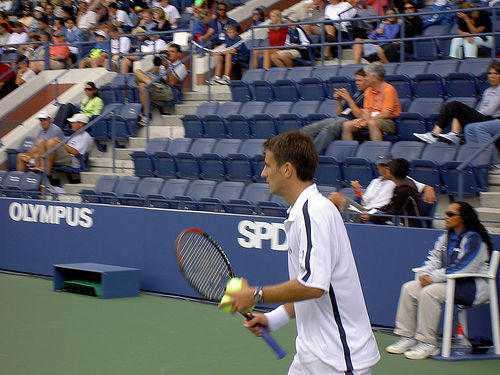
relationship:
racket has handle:
[171, 226, 289, 365] [255, 325, 286, 358]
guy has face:
[225, 142, 379, 371] [258, 147, 287, 196]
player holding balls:
[225, 142, 379, 371] [217, 279, 246, 310]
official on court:
[385, 204, 500, 374] [0, 274, 499, 370]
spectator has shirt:
[346, 66, 406, 147] [364, 84, 406, 117]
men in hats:
[25, 112, 94, 178] [35, 112, 94, 127]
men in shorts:
[25, 112, 94, 178] [15, 147, 77, 173]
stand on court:
[53, 257, 142, 299] [0, 274, 499, 370]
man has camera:
[129, 43, 189, 120] [150, 46, 172, 69]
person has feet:
[412, 54, 499, 143] [412, 126, 463, 148]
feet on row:
[412, 126, 463, 148] [142, 133, 475, 144]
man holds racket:
[225, 142, 379, 371] [171, 226, 289, 365]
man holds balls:
[225, 142, 379, 371] [217, 279, 246, 310]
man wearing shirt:
[341, 148, 403, 221] [353, 169, 434, 222]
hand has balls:
[221, 282, 258, 317] [220, 276, 257, 315]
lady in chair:
[385, 204, 500, 374] [418, 249, 500, 362]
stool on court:
[53, 257, 142, 299] [0, 274, 499, 370]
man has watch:
[225, 142, 379, 371] [250, 287, 270, 310]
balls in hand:
[217, 279, 246, 310] [221, 282, 258, 317]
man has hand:
[225, 142, 379, 371] [221, 282, 258, 317]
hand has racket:
[221, 282, 258, 317] [171, 226, 289, 365]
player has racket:
[225, 142, 379, 371] [171, 226, 289, 365]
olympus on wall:
[5, 197, 95, 228] [0, 192, 494, 352]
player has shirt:
[225, 142, 379, 371] [288, 187, 381, 374]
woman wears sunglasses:
[385, 204, 500, 374] [443, 205, 463, 219]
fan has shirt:
[346, 66, 406, 147] [364, 84, 406, 117]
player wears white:
[225, 142, 379, 371] [288, 187, 381, 374]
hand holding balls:
[216, 279, 260, 314] [217, 279, 246, 310]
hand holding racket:
[216, 279, 260, 314] [171, 226, 289, 365]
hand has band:
[243, 306, 275, 344] [264, 303, 296, 332]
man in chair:
[129, 43, 189, 120] [138, 69, 191, 110]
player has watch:
[225, 142, 379, 371] [250, 287, 270, 310]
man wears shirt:
[341, 148, 403, 221] [353, 169, 434, 222]